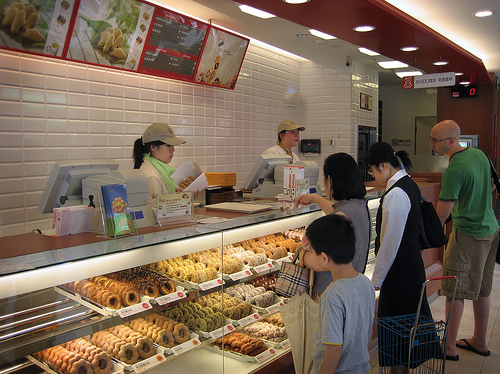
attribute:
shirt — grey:
[313, 273, 372, 371]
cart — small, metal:
[376, 260, 455, 372]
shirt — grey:
[310, 268, 372, 369]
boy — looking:
[301, 212, 377, 372]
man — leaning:
[426, 100, 496, 362]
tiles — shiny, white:
[41, 66, 222, 152]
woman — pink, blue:
[294, 152, 369, 290]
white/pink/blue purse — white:
[269, 246, 311, 295]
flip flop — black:
[444, 337, 489, 363]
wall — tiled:
[61, 94, 122, 131]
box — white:
[169, 162, 211, 198]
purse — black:
[419, 193, 448, 250]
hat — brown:
[275, 120, 309, 132]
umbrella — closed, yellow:
[275, 241, 334, 371]